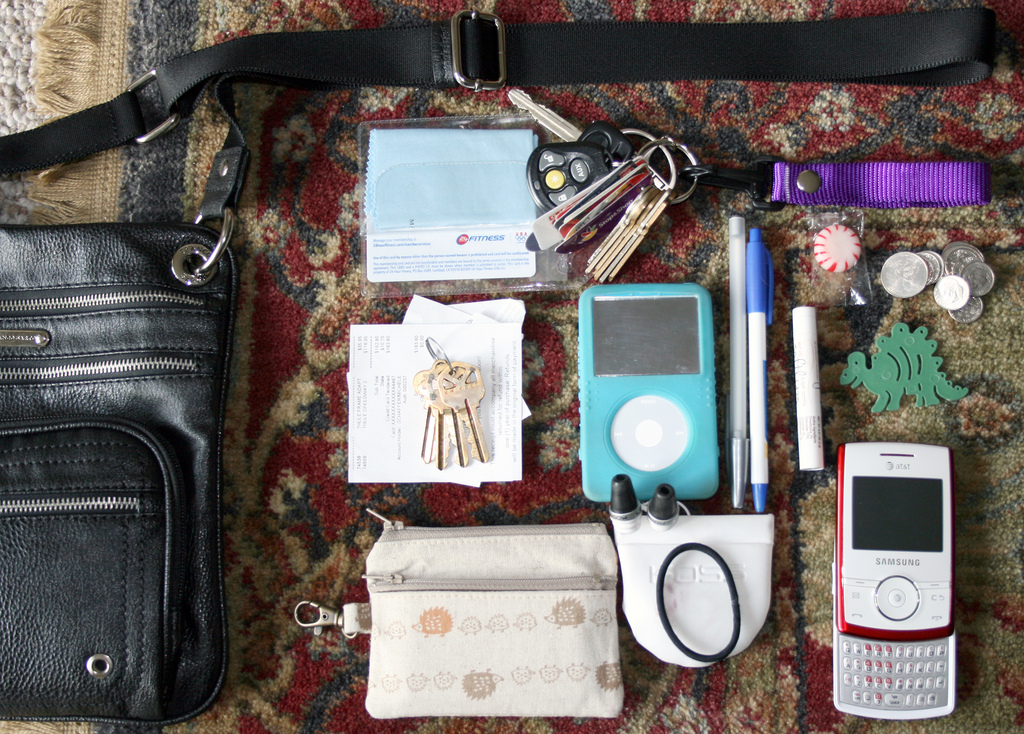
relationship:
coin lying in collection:
[881, 251, 928, 298] [881, 241, 998, 323]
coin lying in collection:
[933, 276, 969, 313] [881, 241, 998, 323]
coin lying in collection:
[914, 245, 943, 285] [881, 241, 998, 323]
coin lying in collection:
[944, 244, 987, 276] [881, 241, 998, 323]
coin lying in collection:
[955, 258, 992, 295] [881, 241, 998, 323]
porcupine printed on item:
[410, 601, 460, 636] [293, 507, 624, 720]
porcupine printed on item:
[452, 612, 483, 638] [293, 507, 624, 720]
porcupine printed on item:
[477, 610, 508, 632] [293, 507, 624, 720]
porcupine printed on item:
[508, 610, 539, 632] [293, 507, 624, 720]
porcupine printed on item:
[536, 593, 589, 632] [293, 507, 624, 720]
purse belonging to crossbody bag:
[0, 215, 243, 727] [4, 1, 992, 727]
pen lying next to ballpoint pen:
[724, 214, 751, 513] [744, 227, 776, 513]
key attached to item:
[506, 89, 634, 169] [685, 161, 989, 211]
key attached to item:
[584, 186, 679, 284] [685, 161, 989, 211]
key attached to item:
[581, 178, 657, 276] [685, 161, 989, 211]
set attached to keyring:
[413, 337, 490, 471] [424, 336, 457, 369]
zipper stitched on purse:
[4, 495, 145, 513] [4, 217, 244, 730]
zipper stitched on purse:
[2, 350, 201, 387] [4, 217, 244, 730]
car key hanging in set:
[411, 357, 448, 464] [410, 351, 493, 475]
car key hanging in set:
[430, 359, 457, 476] [410, 351, 493, 475]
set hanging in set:
[413, 337, 490, 471] [410, 351, 493, 475]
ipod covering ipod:
[580, 282, 722, 503] [580, 282, 722, 503]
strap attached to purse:
[0, 1, 990, 226] [4, 217, 244, 730]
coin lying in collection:
[875, 243, 930, 302] [875, 236, 992, 327]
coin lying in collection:
[931, 273, 975, 312] [875, 236, 992, 327]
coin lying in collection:
[933, 276, 969, 313] [875, 236, 992, 327]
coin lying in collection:
[959, 261, 994, 298] [875, 236, 992, 327]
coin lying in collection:
[938, 230, 986, 274] [875, 236, 992, 327]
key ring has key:
[490, 82, 994, 286] [499, 78, 644, 152]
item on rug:
[840, 322, 969, 412] [250, 195, 328, 565]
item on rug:
[795, 418, 970, 717] [237, 189, 339, 684]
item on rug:
[840, 322, 969, 412] [203, 189, 342, 455]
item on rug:
[726, 124, 992, 250] [226, 366, 324, 524]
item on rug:
[840, 322, 969, 412] [239, 441, 360, 565]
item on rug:
[814, 294, 989, 442] [235, 437, 350, 548]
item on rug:
[830, 442, 956, 722] [4, 6, 1022, 724]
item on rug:
[596, 475, 772, 668] [4, 6, 1022, 724]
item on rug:
[287, 503, 629, 732] [4, 6, 1022, 724]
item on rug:
[336, 292, 544, 498] [4, 6, 1022, 724]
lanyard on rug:
[358, 112, 569, 299] [4, 6, 1022, 724]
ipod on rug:
[580, 282, 722, 503] [4, 6, 1022, 724]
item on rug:
[840, 322, 969, 412] [4, 6, 1022, 724]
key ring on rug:
[506, 86, 993, 284] [4, 6, 1022, 724]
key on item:
[417, 358, 437, 460] [347, 292, 533, 488]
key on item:
[430, 369, 448, 467] [347, 292, 533, 488]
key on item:
[448, 371, 470, 462] [347, 292, 533, 488]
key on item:
[459, 362, 485, 458] [347, 292, 533, 488]